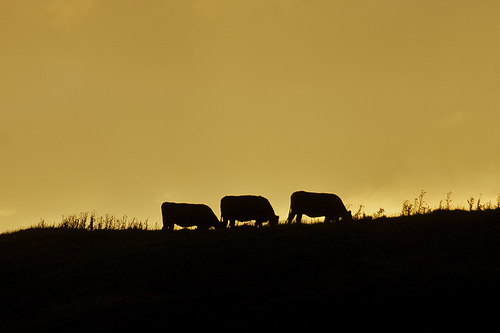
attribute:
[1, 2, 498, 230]
sky — golden, orange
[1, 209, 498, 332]
hill — black